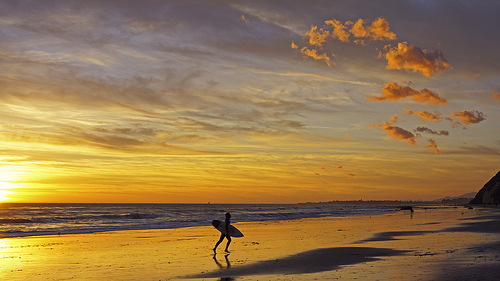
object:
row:
[294, 197, 435, 209]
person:
[210, 210, 232, 254]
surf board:
[209, 219, 247, 239]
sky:
[0, 0, 499, 203]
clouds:
[364, 78, 456, 107]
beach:
[0, 205, 499, 281]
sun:
[0, 152, 39, 203]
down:
[2, 189, 471, 200]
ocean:
[0, 203, 402, 235]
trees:
[303, 197, 471, 204]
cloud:
[366, 37, 458, 78]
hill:
[468, 168, 499, 207]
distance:
[296, 191, 479, 207]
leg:
[223, 237, 232, 250]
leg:
[212, 232, 225, 249]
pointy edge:
[230, 224, 244, 239]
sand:
[0, 206, 499, 280]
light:
[0, 130, 210, 279]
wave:
[0, 210, 167, 237]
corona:
[0, 163, 60, 202]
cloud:
[420, 138, 443, 157]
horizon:
[0, 171, 475, 204]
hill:
[457, 189, 479, 200]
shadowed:
[187, 245, 418, 278]